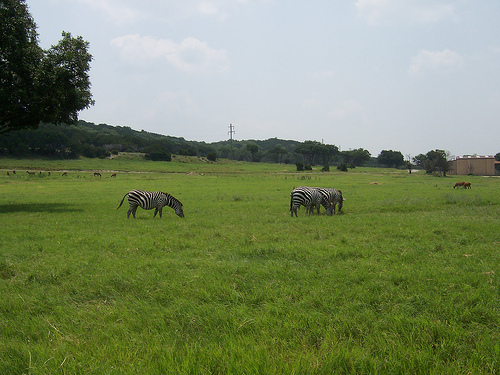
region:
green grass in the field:
[102, 245, 324, 338]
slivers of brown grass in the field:
[20, 332, 85, 364]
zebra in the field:
[101, 180, 200, 225]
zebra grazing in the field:
[109, 167, 389, 236]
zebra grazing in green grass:
[117, 189, 185, 221]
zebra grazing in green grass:
[290, 190, 320, 219]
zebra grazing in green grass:
[322, 187, 347, 213]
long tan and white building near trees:
[446, 151, 498, 175]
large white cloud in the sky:
[103, 35, 228, 72]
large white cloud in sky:
[398, 48, 455, 105]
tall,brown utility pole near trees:
[226, 121, 236, 163]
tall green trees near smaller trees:
[1, 0, 94, 123]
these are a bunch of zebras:
[38, 41, 420, 322]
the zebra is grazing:
[117, 178, 212, 238]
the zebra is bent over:
[121, 176, 193, 221]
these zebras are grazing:
[256, 179, 356, 236]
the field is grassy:
[190, 217, 418, 321]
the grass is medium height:
[188, 264, 323, 339]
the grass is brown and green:
[100, 238, 256, 345]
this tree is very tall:
[18, 22, 108, 113]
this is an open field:
[47, 45, 408, 307]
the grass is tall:
[115, 254, 413, 366]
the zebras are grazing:
[98, 148, 338, 259]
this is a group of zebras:
[285, 168, 347, 220]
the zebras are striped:
[124, 153, 358, 273]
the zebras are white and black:
[61, 123, 332, 235]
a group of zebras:
[103, 160, 367, 217]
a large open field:
[16, 146, 496, 367]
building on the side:
[444, 145, 494, 180]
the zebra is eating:
[106, 177, 201, 229]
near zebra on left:
[119, 184, 193, 227]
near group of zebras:
[284, 181, 349, 221]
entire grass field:
[6, 122, 495, 371]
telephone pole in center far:
[225, 119, 238, 146]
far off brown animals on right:
[450, 179, 477, 191]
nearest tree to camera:
[0, 0, 95, 222]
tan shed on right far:
[453, 151, 498, 183]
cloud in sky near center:
[116, 32, 238, 77]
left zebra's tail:
[116, 189, 130, 214]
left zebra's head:
[173, 199, 186, 219]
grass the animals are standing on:
[253, 255, 331, 298]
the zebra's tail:
[116, 192, 127, 211]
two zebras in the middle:
[291, 183, 343, 213]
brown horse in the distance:
[455, 179, 473, 189]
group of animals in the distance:
[4, 166, 125, 179]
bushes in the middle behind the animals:
[293, 160, 353, 175]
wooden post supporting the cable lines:
[224, 122, 235, 139]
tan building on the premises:
[456, 155, 494, 175]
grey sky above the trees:
[139, 97, 186, 130]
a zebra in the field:
[321, 185, 354, 217]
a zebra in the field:
[124, 183, 197, 225]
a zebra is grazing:
[119, 172, 181, 226]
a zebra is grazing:
[282, 185, 327, 218]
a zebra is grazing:
[326, 183, 352, 222]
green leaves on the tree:
[418, 146, 439, 173]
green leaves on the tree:
[341, 145, 371, 165]